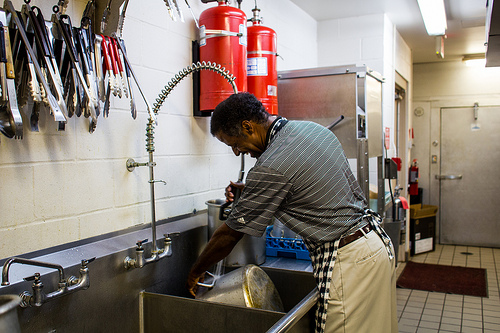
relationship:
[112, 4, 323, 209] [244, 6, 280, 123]
wall has fire extinguisher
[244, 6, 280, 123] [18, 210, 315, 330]
fire extinguisher above sink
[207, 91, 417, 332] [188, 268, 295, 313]
man washes pot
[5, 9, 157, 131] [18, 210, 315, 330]
utensils above sink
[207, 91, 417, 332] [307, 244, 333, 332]
man wears apron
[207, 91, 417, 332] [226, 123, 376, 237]
man wears shirt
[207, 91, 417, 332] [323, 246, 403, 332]
man wears pants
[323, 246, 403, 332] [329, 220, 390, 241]
pants have belt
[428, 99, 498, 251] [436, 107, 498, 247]
cooler has door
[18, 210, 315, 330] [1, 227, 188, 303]
sink has faucets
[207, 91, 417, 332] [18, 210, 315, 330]
man stands by sink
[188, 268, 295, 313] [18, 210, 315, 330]
pot in sink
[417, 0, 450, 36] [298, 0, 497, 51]
light on ceiling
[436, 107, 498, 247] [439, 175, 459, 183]
door has handle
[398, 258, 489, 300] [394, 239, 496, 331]
rug on floor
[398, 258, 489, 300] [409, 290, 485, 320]
rug on tiles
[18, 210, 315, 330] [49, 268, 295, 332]
sink has basins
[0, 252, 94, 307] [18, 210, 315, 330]
faucet on sink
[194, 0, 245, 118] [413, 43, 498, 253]
fire extinguisher on wall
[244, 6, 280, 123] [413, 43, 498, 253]
fire extinguisher on wall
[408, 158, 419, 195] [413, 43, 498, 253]
fire extinguisher on wall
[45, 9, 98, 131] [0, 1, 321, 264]
utensils hanging wall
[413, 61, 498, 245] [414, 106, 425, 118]
wall on clock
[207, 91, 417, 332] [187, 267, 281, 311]
man washing pot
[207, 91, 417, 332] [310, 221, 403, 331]
man in pants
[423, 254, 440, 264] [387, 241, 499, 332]
tile on floor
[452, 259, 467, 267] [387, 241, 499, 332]
tile on floor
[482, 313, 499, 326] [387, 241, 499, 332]
tile on floor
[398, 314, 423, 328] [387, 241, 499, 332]
tile on floor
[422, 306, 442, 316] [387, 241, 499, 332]
tile on floor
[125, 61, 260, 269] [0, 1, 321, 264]
faucet fastened on wall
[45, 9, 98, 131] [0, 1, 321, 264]
utensils hanging on wall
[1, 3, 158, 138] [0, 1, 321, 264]
cooking tools on wall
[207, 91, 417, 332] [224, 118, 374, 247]
man wearing shirt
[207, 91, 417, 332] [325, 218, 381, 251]
man wearing belt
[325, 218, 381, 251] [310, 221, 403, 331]
belt wearing pants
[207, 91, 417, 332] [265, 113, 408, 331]
man wearing apron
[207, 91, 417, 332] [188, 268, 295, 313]
man washing pot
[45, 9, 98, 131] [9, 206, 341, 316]
utensils above sink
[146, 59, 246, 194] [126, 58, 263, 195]
coil around tap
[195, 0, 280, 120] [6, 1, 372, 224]
tanks on wall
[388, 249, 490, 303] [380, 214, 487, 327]
mat on floor